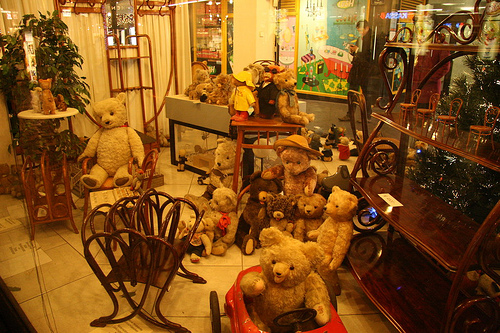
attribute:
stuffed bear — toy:
[236, 223, 332, 326]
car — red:
[197, 254, 349, 330]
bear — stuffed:
[212, 51, 270, 119]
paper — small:
[376, 190, 401, 205]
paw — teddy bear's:
[84, 175, 99, 190]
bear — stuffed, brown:
[248, 124, 317, 184]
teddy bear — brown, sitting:
[239, 224, 337, 329]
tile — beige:
[3, 236, 74, 306]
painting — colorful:
[291, 0, 356, 100]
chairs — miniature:
[398, 87, 419, 122]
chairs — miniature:
[416, 90, 440, 130]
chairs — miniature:
[433, 95, 462, 134]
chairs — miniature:
[466, 105, 496, 150]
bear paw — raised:
[241, 269, 267, 296]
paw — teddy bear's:
[240, 275, 268, 296]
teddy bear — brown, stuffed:
[320, 189, 367, 265]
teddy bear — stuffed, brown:
[246, 224, 322, 309]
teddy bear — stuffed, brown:
[269, 128, 316, 193]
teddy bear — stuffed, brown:
[255, 184, 298, 240]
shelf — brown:
[332, 22, 499, 331]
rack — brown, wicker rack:
[109, 183, 162, 253]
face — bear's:
[262, 240, 305, 282]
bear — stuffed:
[245, 220, 347, 325]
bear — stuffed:
[299, 177, 370, 268]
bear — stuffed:
[294, 177, 342, 256]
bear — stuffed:
[193, 176, 238, 241]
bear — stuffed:
[274, 68, 322, 132]